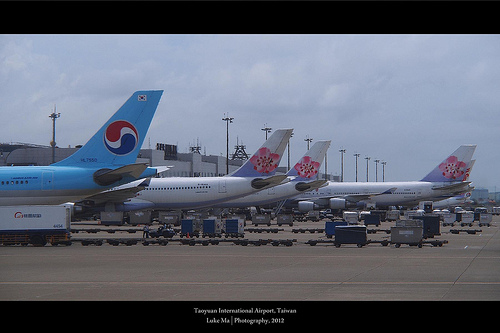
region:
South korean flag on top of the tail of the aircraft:
[129, 86, 156, 108]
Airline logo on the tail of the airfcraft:
[98, 118, 143, 156]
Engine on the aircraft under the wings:
[293, 198, 356, 213]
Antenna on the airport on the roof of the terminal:
[231, 136, 251, 161]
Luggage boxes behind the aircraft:
[325, 222, 428, 249]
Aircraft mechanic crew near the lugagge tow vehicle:
[138, 221, 154, 238]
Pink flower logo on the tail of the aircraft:
[249, 146, 284, 175]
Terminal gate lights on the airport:
[336, 148, 394, 173]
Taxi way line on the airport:
[0, 272, 499, 286]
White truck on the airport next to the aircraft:
[0, 201, 77, 247]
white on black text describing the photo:
[189, 301, 301, 328]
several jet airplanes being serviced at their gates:
[5, 36, 495, 300]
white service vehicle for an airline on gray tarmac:
[0, 202, 77, 244]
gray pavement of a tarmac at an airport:
[1, 247, 492, 296]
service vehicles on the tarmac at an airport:
[91, 202, 476, 249]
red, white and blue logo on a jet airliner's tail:
[104, 119, 141, 159]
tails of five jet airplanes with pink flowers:
[235, 128, 477, 188]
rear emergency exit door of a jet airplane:
[215, 176, 230, 195]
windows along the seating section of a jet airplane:
[129, 185, 214, 190]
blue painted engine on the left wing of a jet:
[79, 195, 156, 213]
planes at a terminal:
[9, 84, 488, 234]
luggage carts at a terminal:
[117, 208, 499, 245]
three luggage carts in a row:
[175, 213, 246, 237]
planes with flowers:
[249, 129, 476, 195]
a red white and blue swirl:
[99, 116, 140, 166]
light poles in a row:
[337, 143, 392, 180]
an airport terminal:
[4, 134, 281, 214]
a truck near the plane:
[2, 199, 72, 234]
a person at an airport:
[137, 222, 152, 237]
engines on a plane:
[296, 194, 351, 209]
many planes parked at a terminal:
[3, 125, 472, 242]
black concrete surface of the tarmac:
[246, 254, 388, 295]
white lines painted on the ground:
[453, 237, 485, 256]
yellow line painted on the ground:
[312, 272, 480, 292]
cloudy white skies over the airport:
[291, 43, 397, 121]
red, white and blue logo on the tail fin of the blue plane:
[91, 121, 146, 158]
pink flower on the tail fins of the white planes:
[247, 145, 476, 183]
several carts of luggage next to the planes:
[85, 208, 442, 248]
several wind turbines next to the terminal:
[198, 111, 402, 177]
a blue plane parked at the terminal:
[0, 86, 165, 212]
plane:
[14, 77, 168, 274]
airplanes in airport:
[151, 113, 471, 230]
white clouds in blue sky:
[24, 36, 59, 90]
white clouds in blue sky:
[66, 51, 113, 82]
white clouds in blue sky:
[171, 43, 228, 68]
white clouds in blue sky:
[181, 73, 209, 93]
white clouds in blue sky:
[243, 46, 295, 81]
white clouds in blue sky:
[286, 34, 328, 69]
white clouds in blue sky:
[371, 51, 425, 109]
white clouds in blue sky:
[324, 93, 404, 147]